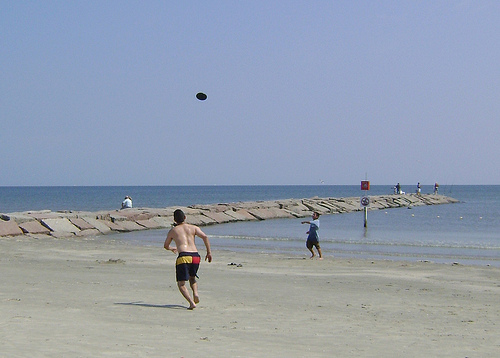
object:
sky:
[0, 0, 500, 185]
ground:
[395, 145, 412, 190]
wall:
[98, 208, 165, 228]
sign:
[360, 195, 371, 207]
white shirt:
[116, 190, 140, 210]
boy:
[163, 209, 212, 309]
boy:
[301, 212, 324, 260]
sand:
[230, 273, 500, 358]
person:
[116, 195, 133, 211]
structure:
[167, 186, 315, 228]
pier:
[0, 192, 460, 238]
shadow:
[113, 301, 188, 310]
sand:
[0, 253, 257, 358]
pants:
[305, 240, 320, 249]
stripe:
[177, 256, 201, 266]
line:
[385, 212, 483, 219]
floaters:
[407, 207, 415, 217]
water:
[0, 184, 500, 266]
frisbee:
[196, 92, 208, 100]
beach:
[0, 234, 500, 358]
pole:
[363, 171, 367, 228]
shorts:
[175, 251, 201, 281]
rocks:
[73, 206, 176, 226]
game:
[120, 90, 323, 311]